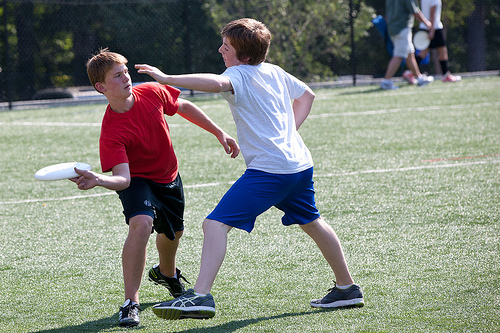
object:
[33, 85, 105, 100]
car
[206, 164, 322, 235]
shorts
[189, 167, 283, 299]
leg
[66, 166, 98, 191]
hand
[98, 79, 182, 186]
shirt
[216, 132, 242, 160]
hands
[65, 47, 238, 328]
boy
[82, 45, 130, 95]
hair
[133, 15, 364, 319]
kids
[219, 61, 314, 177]
shirt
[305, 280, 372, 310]
shoes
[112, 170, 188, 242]
shorts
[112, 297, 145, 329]
shoes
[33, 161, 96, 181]
disk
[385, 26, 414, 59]
shorts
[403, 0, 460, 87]
man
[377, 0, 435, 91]
people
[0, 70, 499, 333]
field